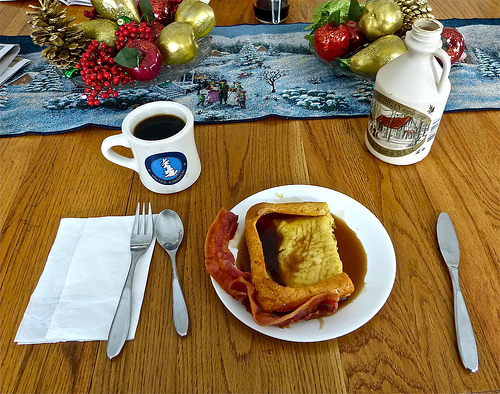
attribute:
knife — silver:
[437, 207, 477, 369]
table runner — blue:
[2, 16, 495, 113]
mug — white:
[98, 100, 205, 189]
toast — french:
[187, 175, 353, 315]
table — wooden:
[2, 1, 499, 392]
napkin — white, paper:
[19, 213, 154, 346]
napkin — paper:
[32, 209, 157, 346]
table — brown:
[8, 60, 498, 364]